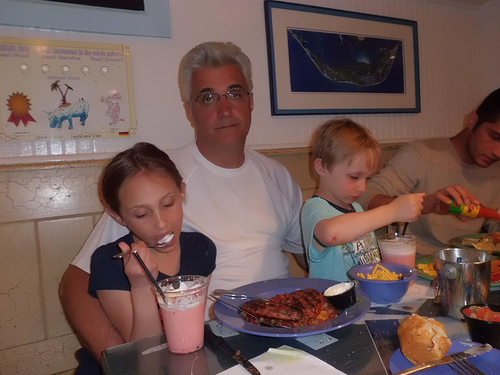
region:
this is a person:
[87, 137, 217, 368]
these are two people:
[70, 35, 305, 370]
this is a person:
[297, 115, 419, 285]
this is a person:
[375, 88, 498, 284]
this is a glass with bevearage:
[155, 272, 207, 353]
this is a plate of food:
[209, 272, 374, 339]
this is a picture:
[2, 27, 139, 138]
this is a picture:
[263, 2, 426, 118]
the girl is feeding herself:
[95, 137, 214, 374]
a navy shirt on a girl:
[69, 226, 214, 373]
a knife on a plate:
[398, 340, 496, 374]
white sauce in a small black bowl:
[325, 277, 356, 311]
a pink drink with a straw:
[132, 249, 209, 353]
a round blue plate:
[212, 272, 371, 344]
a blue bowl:
[346, 255, 419, 307]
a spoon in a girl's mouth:
[109, 230, 175, 259]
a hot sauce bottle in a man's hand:
[438, 194, 499, 221]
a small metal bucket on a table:
[430, 241, 493, 323]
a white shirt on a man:
[66, 143, 304, 327]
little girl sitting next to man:
[86, 143, 216, 345]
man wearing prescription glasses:
[58, 40, 304, 373]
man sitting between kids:
[57, 42, 310, 370]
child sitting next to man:
[300, 115, 426, 288]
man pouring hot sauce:
[358, 83, 498, 259]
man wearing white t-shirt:
[56, 39, 303, 370]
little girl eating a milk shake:
[82, 140, 214, 347]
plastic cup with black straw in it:
[134, 252, 208, 354]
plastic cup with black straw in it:
[377, 221, 417, 267]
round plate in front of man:
[213, 276, 369, 339]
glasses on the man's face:
[198, 83, 247, 104]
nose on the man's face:
[219, 96, 232, 119]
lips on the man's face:
[215, 121, 238, 132]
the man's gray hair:
[177, 41, 267, 91]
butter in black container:
[327, 284, 357, 301]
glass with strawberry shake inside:
[155, 278, 209, 355]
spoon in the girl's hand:
[112, 234, 190, 259]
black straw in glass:
[133, 253, 168, 295]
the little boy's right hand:
[391, 193, 425, 224]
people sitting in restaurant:
[7, 2, 498, 373]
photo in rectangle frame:
[263, 4, 422, 114]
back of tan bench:
[0, 143, 417, 372]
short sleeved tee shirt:
[75, 145, 302, 306]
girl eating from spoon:
[99, 143, 187, 264]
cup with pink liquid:
[155, 273, 209, 354]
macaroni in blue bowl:
[352, 262, 417, 306]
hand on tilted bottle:
[435, 184, 498, 225]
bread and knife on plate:
[388, 314, 489, 374]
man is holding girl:
[54, 39, 306, 374]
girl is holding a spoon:
[81, 144, 218, 344]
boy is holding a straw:
[305, 117, 422, 240]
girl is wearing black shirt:
[86, 147, 209, 345]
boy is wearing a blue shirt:
[295, 119, 394, 284]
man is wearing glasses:
[170, 39, 265, 152]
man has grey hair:
[173, 42, 261, 155]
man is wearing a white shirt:
[61, 39, 317, 296]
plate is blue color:
[207, 268, 374, 350]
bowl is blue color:
[335, 255, 430, 316]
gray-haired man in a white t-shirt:
[58, 40, 303, 360]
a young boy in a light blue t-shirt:
[300, 117, 425, 279]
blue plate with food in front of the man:
[212, 276, 371, 336]